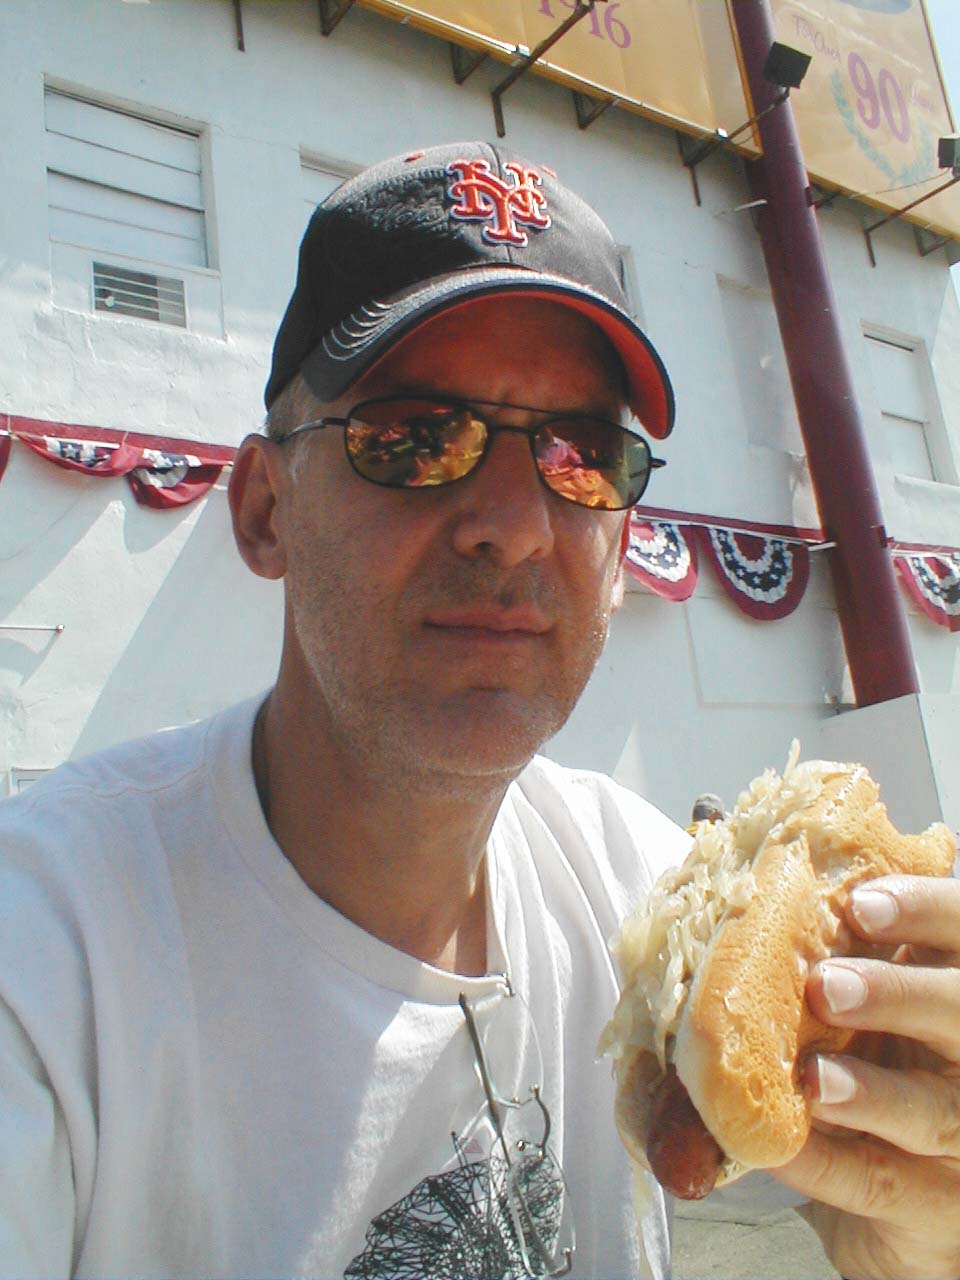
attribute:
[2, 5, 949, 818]
whitewall — wall, white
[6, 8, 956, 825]
building — white